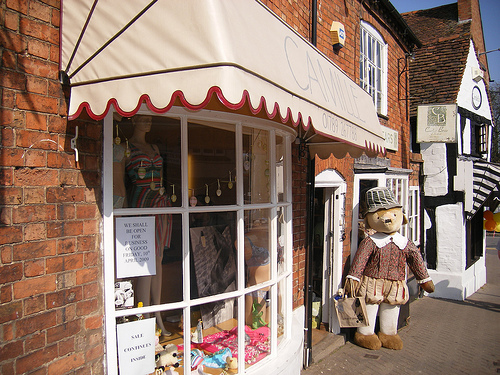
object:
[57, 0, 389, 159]
awning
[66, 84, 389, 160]
trim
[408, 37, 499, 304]
next door building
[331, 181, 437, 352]
teddy bear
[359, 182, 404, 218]
hat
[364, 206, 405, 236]
face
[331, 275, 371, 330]
bag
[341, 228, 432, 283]
jacket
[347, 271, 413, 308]
slops [really]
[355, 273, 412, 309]
slops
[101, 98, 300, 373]
window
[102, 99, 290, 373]
frame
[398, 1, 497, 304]
building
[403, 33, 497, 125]
roof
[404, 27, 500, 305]
shop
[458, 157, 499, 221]
awning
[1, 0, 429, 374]
building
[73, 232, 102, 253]
bricks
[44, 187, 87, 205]
brick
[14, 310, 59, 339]
brick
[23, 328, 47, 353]
brick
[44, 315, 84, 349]
brick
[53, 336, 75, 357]
brick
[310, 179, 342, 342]
doorway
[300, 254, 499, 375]
sidewalk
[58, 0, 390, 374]
store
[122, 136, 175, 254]
dress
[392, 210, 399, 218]
eye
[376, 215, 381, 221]
eye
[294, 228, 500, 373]
street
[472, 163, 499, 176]
stripe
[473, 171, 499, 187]
stripe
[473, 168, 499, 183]
stripe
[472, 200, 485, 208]
stripe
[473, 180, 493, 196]
stripe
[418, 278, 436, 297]
paw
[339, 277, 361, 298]
paw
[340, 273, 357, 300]
handle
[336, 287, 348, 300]
toy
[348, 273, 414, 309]
red thru slashes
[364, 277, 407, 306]
red under-fabric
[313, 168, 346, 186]
arch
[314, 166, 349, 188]
under-arch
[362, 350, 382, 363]
small drain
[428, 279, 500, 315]
shadow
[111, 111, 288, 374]
@ least 12 panes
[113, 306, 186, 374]
panes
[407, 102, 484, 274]
detailing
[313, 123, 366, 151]
straight center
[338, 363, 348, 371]
spot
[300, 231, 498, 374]
ground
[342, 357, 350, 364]
spot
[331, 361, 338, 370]
spot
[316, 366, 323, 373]
spot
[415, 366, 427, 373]
spot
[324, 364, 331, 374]
spot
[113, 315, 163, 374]
sign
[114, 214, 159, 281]
sign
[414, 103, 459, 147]
sign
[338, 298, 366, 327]
logo